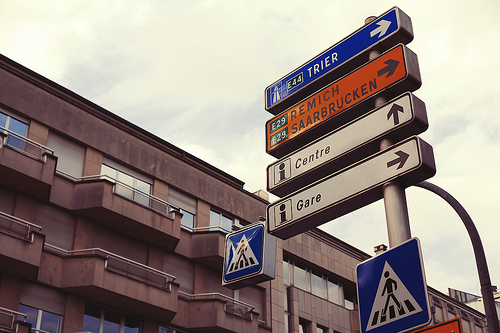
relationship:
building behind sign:
[1, 54, 495, 328] [266, 135, 423, 234]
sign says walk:
[218, 226, 276, 286] [229, 235, 256, 270]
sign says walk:
[357, 237, 431, 332] [379, 268, 403, 313]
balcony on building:
[2, 126, 63, 188] [1, 54, 495, 328]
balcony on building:
[86, 172, 188, 245] [1, 54, 495, 328]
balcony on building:
[2, 209, 51, 279] [1, 54, 495, 328]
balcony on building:
[72, 249, 182, 325] [1, 54, 495, 328]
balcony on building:
[190, 288, 263, 329] [1, 54, 495, 328]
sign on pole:
[266, 135, 423, 234] [384, 183, 421, 332]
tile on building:
[292, 287, 350, 332] [1, 54, 495, 328]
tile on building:
[2, 69, 364, 280] [1, 54, 495, 328]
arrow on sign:
[365, 18, 393, 39] [265, 6, 407, 111]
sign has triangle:
[357, 237, 431, 332] [364, 259, 423, 332]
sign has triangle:
[218, 226, 276, 286] [228, 233, 261, 274]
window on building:
[3, 110, 31, 155] [1, 54, 495, 328]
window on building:
[102, 160, 154, 210] [1, 54, 495, 328]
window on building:
[284, 254, 348, 309] [1, 54, 495, 328]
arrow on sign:
[384, 102, 406, 127] [266, 90, 415, 193]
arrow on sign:
[386, 151, 408, 169] [266, 135, 423, 234]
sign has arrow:
[266, 90, 415, 193] [384, 102, 406, 127]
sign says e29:
[267, 44, 408, 149] [270, 114, 290, 150]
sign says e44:
[265, 6, 407, 111] [286, 71, 304, 91]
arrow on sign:
[386, 103, 404, 125] [266, 135, 423, 234]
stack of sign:
[263, 5, 438, 243] [266, 135, 423, 234]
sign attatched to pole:
[266, 135, 423, 234] [384, 183, 421, 332]